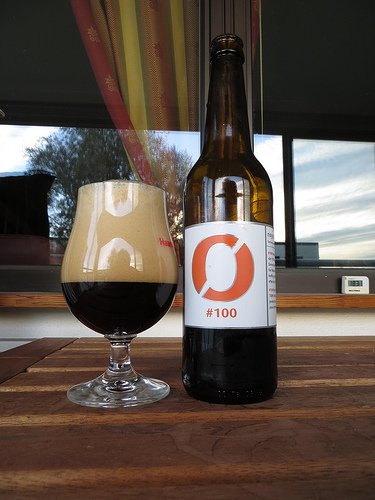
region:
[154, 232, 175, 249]
red writing etched into a glass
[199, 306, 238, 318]
bottle with red label that says #100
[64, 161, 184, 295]
foam fills most of the glass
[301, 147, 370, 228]
partially cloudy outside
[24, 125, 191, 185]
A tree can be seen through a window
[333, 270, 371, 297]
A clock reads 13:31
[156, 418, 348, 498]
stain on table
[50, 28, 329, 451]
A glass and a bottle sit on a wooden table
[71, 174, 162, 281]
Reflections of a window can be seen in the glass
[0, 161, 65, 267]
something dark obstructs part of the window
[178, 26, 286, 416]
bottle sitting on table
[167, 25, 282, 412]
bottle next to wine glass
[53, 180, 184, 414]
wine glass sitting on table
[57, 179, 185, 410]
wine glass next to bottle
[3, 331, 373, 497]
table is brown and wooden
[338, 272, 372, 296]
digital clock on window sill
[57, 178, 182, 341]
wine glass is full of fluid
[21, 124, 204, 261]
reflection of tree in window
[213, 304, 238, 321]
number 100 on bottle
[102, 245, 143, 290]
reflection of person on wine glass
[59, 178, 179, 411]
glass of foaming brown beer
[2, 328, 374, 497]
wooden slatted table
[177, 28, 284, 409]
bottle of brown beer with red and white label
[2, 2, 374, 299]
glass window in restuarant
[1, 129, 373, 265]
blue sky reflected in window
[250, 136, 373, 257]
white jet trails in sky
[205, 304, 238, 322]
red 100 on bottle label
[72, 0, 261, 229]
gold and red damask style curtains in restaurant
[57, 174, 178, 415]
bell shaped beer glass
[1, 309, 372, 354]
white wall behind table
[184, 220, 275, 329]
beer bottle label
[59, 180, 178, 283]
large beer foam head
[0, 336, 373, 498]
brown slatted wood table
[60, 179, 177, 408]
glass of dark beer with large foamy head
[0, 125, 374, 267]
windows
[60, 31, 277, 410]
beer bottle and glass of dark beer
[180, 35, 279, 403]
tall neck brown beer bottle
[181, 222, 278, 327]
orange and white beer label with black lettering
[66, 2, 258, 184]
see through yellow orange and red curtain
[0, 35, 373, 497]
brown beer bottle and glass of dark beer on table